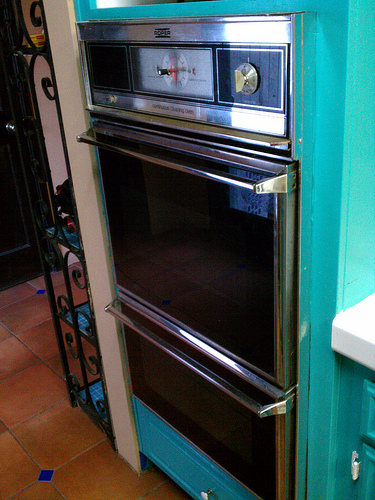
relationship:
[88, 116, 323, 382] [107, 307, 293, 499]
oven and broiler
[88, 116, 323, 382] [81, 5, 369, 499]
oven in wall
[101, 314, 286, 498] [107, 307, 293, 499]
door of broiler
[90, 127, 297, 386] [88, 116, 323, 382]
door for oven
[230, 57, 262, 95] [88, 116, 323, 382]
knob for oven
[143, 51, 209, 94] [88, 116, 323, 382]
clock for oven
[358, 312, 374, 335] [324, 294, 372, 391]
white part of counter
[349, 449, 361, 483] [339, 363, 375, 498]
hinge for cabinet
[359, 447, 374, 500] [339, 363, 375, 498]
door for cabinet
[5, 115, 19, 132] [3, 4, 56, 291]
knob for door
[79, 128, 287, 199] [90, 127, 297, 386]
handle for oven door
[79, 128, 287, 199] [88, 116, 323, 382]
handle for oven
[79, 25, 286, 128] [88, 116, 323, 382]
controls for oven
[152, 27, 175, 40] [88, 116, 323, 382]
name of oven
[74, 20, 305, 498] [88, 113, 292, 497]
unit has two ovens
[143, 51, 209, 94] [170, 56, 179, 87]
clock tells time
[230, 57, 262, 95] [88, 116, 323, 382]
dial for oven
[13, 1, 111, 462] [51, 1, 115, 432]
shelf for items on corner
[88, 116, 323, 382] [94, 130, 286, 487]
oven has two doors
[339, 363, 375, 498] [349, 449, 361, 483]
cabinet has a hinge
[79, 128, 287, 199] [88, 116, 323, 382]
handle metal on oven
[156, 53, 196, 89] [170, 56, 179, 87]
timer had two hands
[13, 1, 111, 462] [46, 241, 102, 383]
shelf with spirals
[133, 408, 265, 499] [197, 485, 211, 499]
drawer has a white handle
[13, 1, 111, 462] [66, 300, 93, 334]
shelf has tiles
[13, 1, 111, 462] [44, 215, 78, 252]
shelf has tiles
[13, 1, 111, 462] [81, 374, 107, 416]
shelf has tiles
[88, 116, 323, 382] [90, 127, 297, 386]
oven has a door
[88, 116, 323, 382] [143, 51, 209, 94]
oven has a clock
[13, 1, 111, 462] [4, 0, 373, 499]
shelf by kitchen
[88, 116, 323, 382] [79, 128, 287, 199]
stove has a handle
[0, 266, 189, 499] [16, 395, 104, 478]
flooring in made of tiles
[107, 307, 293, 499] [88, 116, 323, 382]
broiler under oven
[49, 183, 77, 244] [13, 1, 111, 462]
items on shelf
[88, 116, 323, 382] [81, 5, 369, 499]
oven built in wall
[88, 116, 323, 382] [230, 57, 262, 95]
oven has a knob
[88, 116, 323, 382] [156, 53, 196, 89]
oven has a timer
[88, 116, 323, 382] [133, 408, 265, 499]
oven has a drawer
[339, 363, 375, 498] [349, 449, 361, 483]
cupboard has a hinge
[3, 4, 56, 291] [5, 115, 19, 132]
door has a knob